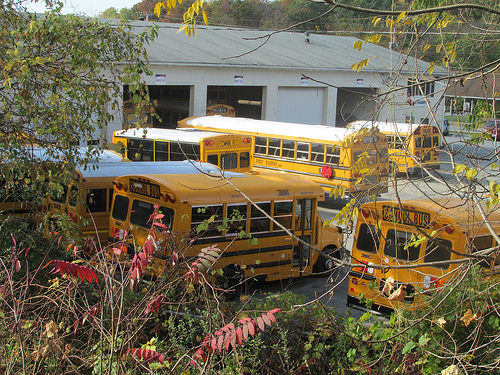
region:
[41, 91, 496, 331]
school bus parking garage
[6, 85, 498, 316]
seven yellow school buses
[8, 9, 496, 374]
trees along the edge of the parking lot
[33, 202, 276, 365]
red leaves on the branches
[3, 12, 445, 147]
gray garage buses are parked in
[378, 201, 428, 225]
black lettering on school bus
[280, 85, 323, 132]
closed garage door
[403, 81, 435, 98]
window on gray building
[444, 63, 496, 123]
brown house with brown roof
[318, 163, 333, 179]
red sign on the bus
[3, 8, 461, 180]
the building is a school bus garage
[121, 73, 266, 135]
buses are in the garage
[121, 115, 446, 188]
buses are waiting in line to be serviced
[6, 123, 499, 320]
the buses are parked on the side of the lot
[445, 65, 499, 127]
the building has a brown shingled roof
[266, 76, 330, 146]
the garage door is closed on this bay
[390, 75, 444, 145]
windows are on the side of the school garage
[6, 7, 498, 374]
bushes and shrubs are around the lot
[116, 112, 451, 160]
the buses have white roofs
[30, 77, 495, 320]
a yard of school buses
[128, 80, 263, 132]
there are buses in the garage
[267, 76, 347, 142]
this garage door is closed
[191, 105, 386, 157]
the roof of the bus is yellow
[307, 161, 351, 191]
this is a red stop sign on the bus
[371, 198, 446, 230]
the letters are black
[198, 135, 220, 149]
red and orange lights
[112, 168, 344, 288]
a yellow short school bus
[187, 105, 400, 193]
this is a full sized school bus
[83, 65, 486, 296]
A bunch of school buses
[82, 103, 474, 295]
The buses are yellow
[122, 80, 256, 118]
The buses are parked in the building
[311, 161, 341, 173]
A stop sign on the side of the bus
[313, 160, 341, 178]
The stop sign is octagon shaped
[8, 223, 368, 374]
Red and green bushes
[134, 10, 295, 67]
The roof is slanted down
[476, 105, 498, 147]
A red car in front of a house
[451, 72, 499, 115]
A house on the other side of the street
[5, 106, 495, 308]
These are school busses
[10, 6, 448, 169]
This is a building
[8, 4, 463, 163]
This is a building to hold busses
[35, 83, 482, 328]
Nine busses in the scene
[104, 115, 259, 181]
This is a small bus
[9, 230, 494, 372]
There are trees in front of the busses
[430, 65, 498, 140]
A house across the street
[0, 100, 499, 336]
School buses are parked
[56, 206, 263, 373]
Red foliage on tree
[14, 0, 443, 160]
The building is white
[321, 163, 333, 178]
the stop sign on the bus is closed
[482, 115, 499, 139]
the red van is parked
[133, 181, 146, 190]
the white stripe on the word school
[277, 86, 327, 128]
the bay door is closed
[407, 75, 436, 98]
the window on the white building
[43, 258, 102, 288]
the leaf is dark red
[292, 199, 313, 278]
the door on the school bus is closed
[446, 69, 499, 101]
the brown roof on the house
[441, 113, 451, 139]
the car behind the white building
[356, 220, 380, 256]
Window of a school bus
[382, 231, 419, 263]
Window of a school bus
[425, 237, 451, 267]
Window of a school bus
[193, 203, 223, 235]
Window of a school bus